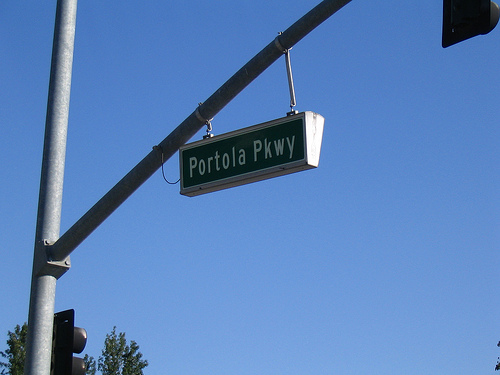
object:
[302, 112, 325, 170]
corner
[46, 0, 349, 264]
pole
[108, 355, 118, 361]
leaves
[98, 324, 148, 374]
tree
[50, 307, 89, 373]
light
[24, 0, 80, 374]
pole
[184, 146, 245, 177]
words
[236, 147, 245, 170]
letter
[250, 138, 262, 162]
letter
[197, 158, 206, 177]
letter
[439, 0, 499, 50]
traffic light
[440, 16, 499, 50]
bottom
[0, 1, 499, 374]
sky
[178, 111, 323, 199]
sign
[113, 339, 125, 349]
leaves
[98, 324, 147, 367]
tree top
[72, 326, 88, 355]
covers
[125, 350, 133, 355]
leaves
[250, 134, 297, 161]
pkwy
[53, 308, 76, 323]
top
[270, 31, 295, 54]
clamps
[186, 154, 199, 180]
p